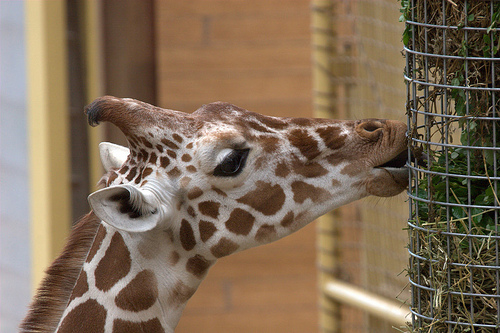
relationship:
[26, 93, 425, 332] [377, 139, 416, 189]
giraffe has mouth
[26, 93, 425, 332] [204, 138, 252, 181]
giraffe has eye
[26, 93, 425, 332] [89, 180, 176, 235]
giraffe has ear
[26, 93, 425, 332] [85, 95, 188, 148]
giraffe has horn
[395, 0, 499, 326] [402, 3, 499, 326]
hay in holder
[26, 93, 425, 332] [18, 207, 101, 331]
giraffe has mane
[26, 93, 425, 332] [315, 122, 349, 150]
giraffe has spot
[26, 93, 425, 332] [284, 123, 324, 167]
giraffe has spot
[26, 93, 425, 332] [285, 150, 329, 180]
giraffe has spot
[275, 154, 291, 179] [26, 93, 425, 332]
spot on giraffe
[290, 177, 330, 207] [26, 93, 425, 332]
spot on giraffe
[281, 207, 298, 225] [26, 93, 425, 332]
spot on giraffe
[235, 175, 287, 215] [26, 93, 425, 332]
spot on giraffe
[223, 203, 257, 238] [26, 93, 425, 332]
spot on giraffe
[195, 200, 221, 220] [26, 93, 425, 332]
spot on giraffe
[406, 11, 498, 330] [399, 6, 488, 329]
plant in feeder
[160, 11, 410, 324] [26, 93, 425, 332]
wall behind giraffe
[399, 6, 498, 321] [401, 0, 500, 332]
leaves in container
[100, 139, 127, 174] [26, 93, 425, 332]
ear of giraffe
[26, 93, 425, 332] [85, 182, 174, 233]
giraffe has ear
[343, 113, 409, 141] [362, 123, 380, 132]
nose has hole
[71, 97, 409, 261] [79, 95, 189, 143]
head has horns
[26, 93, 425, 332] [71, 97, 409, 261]
giraffe has head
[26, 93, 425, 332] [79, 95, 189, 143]
giraffe has horns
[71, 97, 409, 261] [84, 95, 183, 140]
head has horns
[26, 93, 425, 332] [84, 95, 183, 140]
giraffe has horns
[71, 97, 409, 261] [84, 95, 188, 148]
head has horns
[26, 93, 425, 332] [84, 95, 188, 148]
giraffe has horns